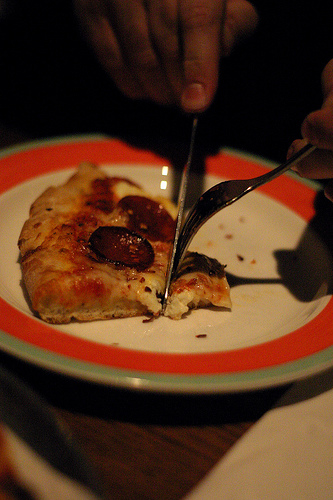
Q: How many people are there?
A: One.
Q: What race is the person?
A: Black.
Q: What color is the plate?
A: White.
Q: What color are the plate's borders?
A: Red and green.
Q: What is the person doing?
A: Cutting food.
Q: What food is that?
A: Pizza.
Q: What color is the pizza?
A: Yellow.